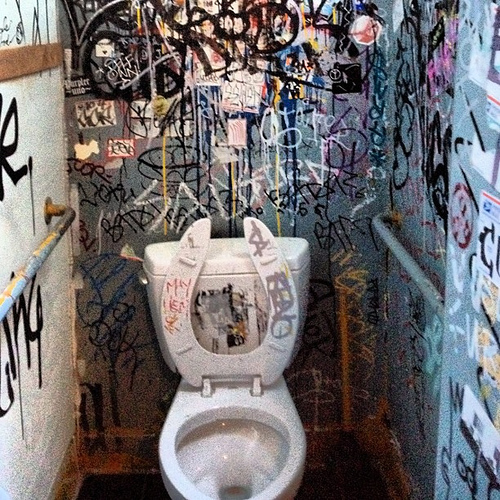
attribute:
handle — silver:
[131, 269, 150, 291]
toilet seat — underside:
[124, 195, 332, 380]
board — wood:
[1, 32, 68, 84]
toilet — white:
[61, 202, 371, 489]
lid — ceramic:
[146, 230, 315, 275]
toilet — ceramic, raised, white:
[138, 205, 320, 498]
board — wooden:
[1, 40, 61, 82]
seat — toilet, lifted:
[161, 214, 301, 389]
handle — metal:
[131, 265, 152, 288]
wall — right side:
[78, 2, 499, 412]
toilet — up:
[100, 198, 357, 498]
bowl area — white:
[171, 405, 294, 498]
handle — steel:
[132, 264, 159, 294]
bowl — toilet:
[152, 376, 309, 499]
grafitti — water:
[192, 284, 254, 352]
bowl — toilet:
[159, 399, 306, 497]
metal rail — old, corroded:
[12, 181, 104, 277]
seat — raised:
[150, 204, 306, 396]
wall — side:
[1, 2, 79, 489]